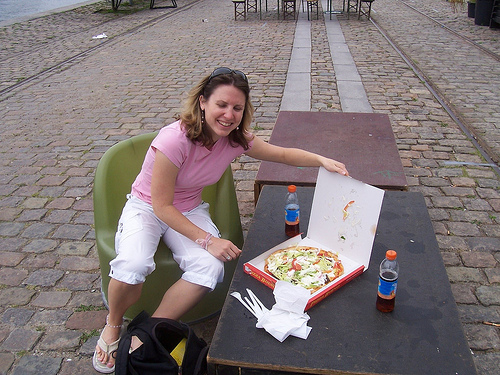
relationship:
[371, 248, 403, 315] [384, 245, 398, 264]
bottle has cap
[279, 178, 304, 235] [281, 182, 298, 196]
bottle has cap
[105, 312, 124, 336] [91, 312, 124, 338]
ankle on ankle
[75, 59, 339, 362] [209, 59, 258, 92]
woman has sunglasses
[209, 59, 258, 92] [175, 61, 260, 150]
sunglasses in hair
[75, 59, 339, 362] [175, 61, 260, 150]
woman has hair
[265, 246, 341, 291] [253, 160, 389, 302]
pizza in box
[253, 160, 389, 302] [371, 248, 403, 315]
box next to bottle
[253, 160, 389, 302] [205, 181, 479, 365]
box on table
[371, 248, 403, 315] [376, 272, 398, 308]
bottle has drink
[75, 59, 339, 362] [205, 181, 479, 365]
woman at table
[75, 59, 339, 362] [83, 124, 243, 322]
woman sitting in chair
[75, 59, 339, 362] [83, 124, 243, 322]
woman in chair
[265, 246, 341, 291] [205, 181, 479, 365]
pizza on table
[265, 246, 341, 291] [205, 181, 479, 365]
pizza on top of table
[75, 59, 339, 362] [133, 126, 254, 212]
woman has shirt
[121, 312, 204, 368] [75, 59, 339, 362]
bag next to woman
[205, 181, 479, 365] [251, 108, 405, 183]
table next to table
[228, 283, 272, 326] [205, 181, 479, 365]
cutlery on top of table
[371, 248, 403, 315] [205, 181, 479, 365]
bottle on table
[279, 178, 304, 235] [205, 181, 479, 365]
bottle on table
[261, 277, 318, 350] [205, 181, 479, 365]
napkins on table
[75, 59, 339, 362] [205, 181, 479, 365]
woman sitting at table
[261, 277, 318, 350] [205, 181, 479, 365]
napkins are on table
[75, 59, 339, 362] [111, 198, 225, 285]
woman has pants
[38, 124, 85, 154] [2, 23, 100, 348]
cobblestones on road